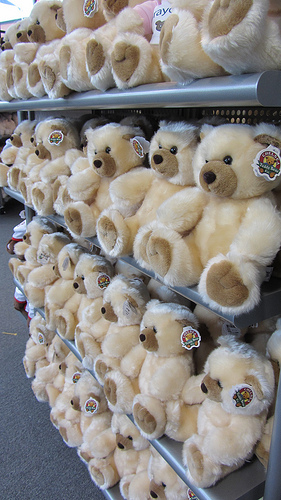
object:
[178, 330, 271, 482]
bears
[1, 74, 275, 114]
shelf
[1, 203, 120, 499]
floor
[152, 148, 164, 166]
nose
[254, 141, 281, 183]
bear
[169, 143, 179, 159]
eye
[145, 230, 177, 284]
foot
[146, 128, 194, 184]
face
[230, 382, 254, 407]
tags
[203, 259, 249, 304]
feet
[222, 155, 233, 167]
eyes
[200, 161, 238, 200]
muzzle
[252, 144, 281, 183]
tag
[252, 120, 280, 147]
ear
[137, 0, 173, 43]
shirt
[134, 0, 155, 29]
pink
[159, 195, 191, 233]
paws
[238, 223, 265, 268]
paws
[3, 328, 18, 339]
yellow strip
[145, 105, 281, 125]
shelf backing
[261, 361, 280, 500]
end post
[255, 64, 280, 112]
edge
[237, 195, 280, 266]
arm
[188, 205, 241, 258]
belly